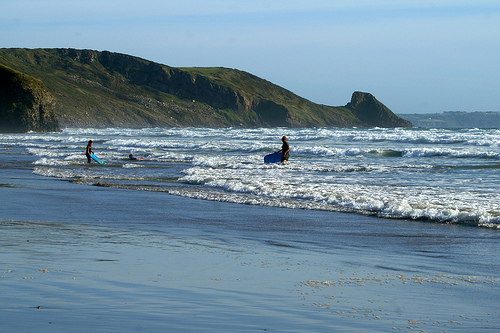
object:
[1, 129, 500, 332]
ocean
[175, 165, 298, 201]
tides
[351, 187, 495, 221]
tides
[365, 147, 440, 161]
tides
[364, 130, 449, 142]
tides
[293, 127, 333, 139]
tides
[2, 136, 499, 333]
beach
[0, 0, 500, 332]
inlet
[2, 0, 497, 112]
blue sky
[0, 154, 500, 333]
shoreline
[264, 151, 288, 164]
board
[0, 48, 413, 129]
cliff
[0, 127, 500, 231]
waves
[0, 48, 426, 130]
hill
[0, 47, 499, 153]
background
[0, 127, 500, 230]
foam bubbles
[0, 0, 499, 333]
scene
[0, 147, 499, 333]
shore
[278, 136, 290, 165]
man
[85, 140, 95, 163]
man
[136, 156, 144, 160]
red trunks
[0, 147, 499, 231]
coastline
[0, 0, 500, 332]
photo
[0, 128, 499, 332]
water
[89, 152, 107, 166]
board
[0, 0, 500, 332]
outside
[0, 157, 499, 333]
sand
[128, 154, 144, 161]
person